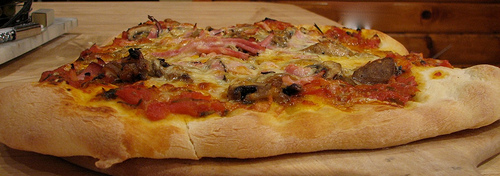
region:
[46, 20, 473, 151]
three slices of pizza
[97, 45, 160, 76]
burger on a slice of pizza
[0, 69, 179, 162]
brown crust on a pizza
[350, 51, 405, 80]
burger on a slice of pizza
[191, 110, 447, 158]
crust on pizza slice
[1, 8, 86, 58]
metal cutter to the left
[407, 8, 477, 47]
wooden table under the pizza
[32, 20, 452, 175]
a pizza on a table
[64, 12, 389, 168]
a table with pizza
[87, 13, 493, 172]
a cooked pizza on a table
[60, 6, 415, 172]
a pizza that is sliced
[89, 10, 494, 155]
a pizza that is cut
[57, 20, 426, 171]
slices of baked pizza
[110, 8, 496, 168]
cheese melted on a pizza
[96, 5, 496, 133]
tomato sauce on pizza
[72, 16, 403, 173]
pizza with toppings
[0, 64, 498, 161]
lightly browned pizza crust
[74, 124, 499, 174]
wooden pizza board under a pizza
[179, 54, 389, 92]
melted cheese on pizza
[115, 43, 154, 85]
chunk of meat on pizza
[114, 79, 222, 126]
red chunky sauce on pizza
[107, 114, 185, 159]
greasy spot on pizza crust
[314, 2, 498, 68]
drawers behind pizza on table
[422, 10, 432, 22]
black knob on drawer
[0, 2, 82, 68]
metal object sitting on table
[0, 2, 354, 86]
wooden table that pizza is sitting on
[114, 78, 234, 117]
cooked pepperoni on pizza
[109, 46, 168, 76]
cooked sausage on pizza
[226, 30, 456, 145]
cheese, sausage and pepperoni pizza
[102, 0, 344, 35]
light brown wood table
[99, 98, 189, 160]
cooked cheese on cruts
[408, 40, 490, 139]
cooked brown crust of pizza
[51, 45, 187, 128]
sausage, cheese and pepperoni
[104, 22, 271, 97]
toppings on cooked pizza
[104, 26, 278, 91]
A pizza on the table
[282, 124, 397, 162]
Dough on the pizza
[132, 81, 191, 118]
Tomatoes on the pizza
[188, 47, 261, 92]
Eggs on the pizza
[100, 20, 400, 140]
A pizza in the photo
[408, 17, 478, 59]
A table in the room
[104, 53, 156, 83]
Meat on the pizza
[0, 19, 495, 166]
very large slice of pizza with toppings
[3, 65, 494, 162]
crust along the edge of the pizza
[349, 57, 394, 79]
piece of a meat topping on pizza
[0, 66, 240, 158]
brown crust of pizza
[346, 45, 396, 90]
sausage meat on top pizza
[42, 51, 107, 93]
ham meat on top pizza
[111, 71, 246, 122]
cheese on top pizza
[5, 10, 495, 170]
pizza on top of pizza board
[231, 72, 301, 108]
black olives on top pizza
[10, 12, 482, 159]
half of pizza on board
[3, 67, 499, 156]
Crust of a pizza slice on a table.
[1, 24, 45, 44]
Silver item to the left of the pizza.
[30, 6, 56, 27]
Brown block to the left of the pizza.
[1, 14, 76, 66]
Gray and white marble board.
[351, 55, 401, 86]
Large piece of meat on the left front.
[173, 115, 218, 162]
Crack in the middle of the pizza crust.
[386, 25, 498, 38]
Space in between two wooden boards.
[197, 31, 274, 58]
Three piece of ham in the middle of pizza.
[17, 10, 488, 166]
the pizza is on the wooden chopping block